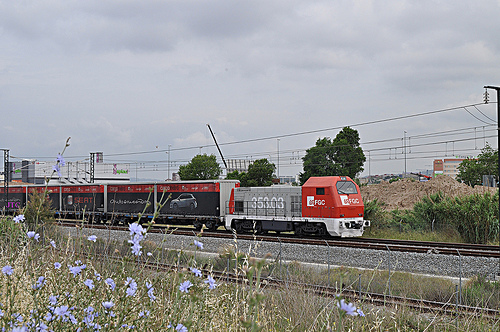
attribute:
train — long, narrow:
[37, 162, 382, 232]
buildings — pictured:
[11, 154, 135, 184]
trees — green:
[179, 124, 369, 185]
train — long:
[14, 173, 373, 242]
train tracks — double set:
[7, 211, 498, 322]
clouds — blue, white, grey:
[0, 3, 497, 173]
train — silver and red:
[0, 175, 375, 237]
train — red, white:
[0, 170, 370, 240]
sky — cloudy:
[19, 7, 301, 131]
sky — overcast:
[11, 8, 352, 134]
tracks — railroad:
[331, 223, 499, 323]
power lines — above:
[377, 109, 498, 180]